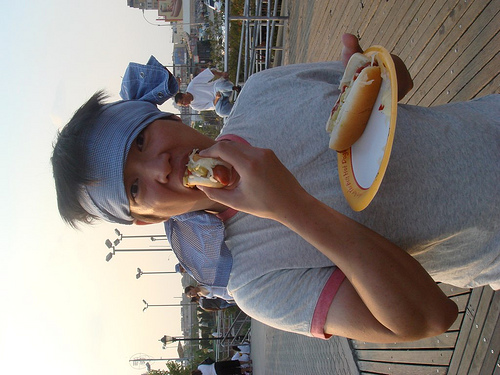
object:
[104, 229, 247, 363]
lamp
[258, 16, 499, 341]
deck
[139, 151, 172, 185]
nose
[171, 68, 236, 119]
man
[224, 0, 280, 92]
fence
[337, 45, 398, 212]
plate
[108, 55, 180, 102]
knot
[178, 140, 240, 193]
oven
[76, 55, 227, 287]
bandana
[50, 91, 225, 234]
head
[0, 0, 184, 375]
clouds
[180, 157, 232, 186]
hot dog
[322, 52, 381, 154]
hot dog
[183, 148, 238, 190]
bun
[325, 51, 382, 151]
bun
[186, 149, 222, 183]
onions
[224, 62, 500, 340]
shirt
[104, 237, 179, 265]
light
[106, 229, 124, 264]
street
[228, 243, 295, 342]
shoulder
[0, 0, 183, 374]
sky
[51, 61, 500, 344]
man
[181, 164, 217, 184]
mustard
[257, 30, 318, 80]
sidewalk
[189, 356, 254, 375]
person